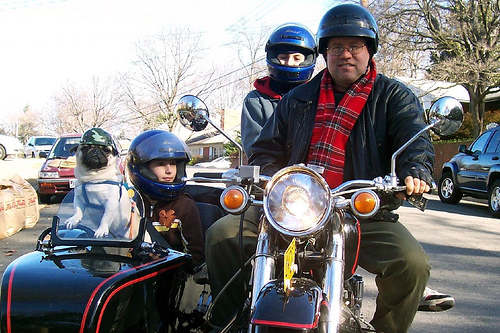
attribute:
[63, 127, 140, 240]
dog — chubby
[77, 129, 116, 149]
helmet — camo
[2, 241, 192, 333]
sidecar — black, red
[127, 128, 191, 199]
helmet — blue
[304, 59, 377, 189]
scarf — red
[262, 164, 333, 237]
headlight — on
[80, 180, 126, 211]
harness — blue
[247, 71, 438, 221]
jacket — black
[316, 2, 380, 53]
helmet — black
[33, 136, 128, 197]
car — parked, red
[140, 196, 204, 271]
jacket — brown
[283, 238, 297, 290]
plate — yellow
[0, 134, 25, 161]
suv — white